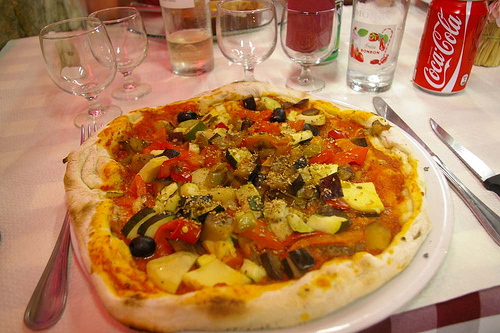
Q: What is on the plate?
A: Pizza.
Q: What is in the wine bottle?
A: Wine.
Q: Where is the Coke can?
A: Above the knife.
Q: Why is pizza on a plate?
A: To be eaten.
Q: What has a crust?
A: The pizza.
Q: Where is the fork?
A: To the left of the plate.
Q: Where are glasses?
A: On the table.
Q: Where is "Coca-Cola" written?
A: On red can.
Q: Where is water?
A: In a glass.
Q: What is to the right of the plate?
A: Butter knife.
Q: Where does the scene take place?
A: In a restaurant.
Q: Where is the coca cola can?
A: To the right of the glasses.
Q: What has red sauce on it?
A: Pizza.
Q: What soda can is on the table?
A: Coca Cola.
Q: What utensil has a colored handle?
A: Knife.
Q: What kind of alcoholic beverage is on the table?
A: Wine.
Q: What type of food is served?
A: Pizza.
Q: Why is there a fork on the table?
A: To eat with.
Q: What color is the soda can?
A: Red.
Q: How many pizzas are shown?
A: One.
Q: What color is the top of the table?
A: White.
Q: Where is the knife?
A: Right side.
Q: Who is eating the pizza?
A: No one.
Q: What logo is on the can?
A: Coca-Cola.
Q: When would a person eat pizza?
A: At lunch.